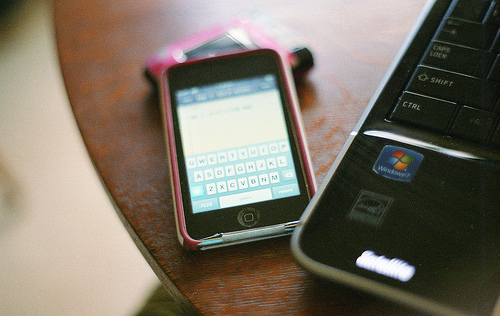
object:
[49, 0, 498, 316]
desk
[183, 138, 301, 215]
keyboard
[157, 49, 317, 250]
cover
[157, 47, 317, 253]
cellphone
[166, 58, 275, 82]
interface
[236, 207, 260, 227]
button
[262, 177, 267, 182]
letter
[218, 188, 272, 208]
space bar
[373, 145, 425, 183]
sticker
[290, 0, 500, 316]
computer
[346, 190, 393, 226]
sticker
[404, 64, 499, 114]
key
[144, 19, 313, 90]
case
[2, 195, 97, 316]
floor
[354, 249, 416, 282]
logo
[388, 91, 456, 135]
button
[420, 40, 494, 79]
button